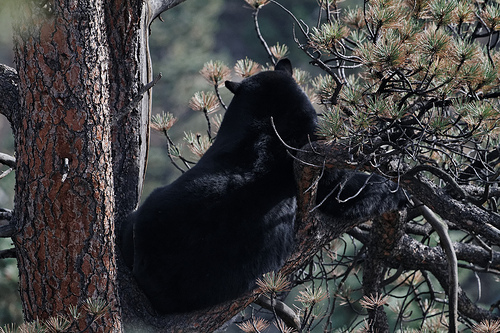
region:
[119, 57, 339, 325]
black bear in a tree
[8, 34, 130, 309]
tree trunk of a pine tree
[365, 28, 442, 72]
pine needles in the tree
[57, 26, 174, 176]
two trees close together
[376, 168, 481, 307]
tree limbs twisted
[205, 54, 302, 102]
ears on a bear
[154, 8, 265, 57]
blurred trees in the distance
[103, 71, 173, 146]
small limb coming off the tree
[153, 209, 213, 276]
black fur on a bear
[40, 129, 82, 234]
red bark on a tree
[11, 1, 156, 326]
two pine tree trunks close togther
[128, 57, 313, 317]
a black bear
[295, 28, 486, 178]
limbs with green and brown leaves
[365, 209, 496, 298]
a branch on a pine tree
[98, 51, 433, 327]
a bear in a tree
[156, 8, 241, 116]
trees in the back ground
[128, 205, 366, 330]
a limb to a pine tree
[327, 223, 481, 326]
limbs to a pine tree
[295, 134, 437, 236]
leg of the bear on a limb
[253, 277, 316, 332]
a limb to a pine tree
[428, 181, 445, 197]
part of a branch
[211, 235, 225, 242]
back of a cat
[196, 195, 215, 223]
back of a cat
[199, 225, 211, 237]
edge of a cat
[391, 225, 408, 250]
part of a a branch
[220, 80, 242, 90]
The left ear of the black bear.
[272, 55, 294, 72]
The right ear of the black bear.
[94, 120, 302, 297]
The body of the black bear.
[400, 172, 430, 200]
The paw of the black bear.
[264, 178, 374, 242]
The right arm of the bear's arm.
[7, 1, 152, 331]
The tree trunks on the left.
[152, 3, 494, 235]
The pine needles on the branches of the tree.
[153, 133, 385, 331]
The thick branch the bear is sitting on.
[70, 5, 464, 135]
The blurred trees in the background.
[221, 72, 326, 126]
The head of the bear.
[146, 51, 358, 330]
Black bear in a tree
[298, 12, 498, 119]
Small needles on a tree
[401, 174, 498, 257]
Small brown tree limb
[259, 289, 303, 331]
Small brown tree limb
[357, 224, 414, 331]
Small brown tree limb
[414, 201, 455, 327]
Small brown tree limb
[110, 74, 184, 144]
Small brown tree limb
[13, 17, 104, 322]
Large brown tree trunk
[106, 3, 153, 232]
Large brown tree trunk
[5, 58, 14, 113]
Small brown tree limb